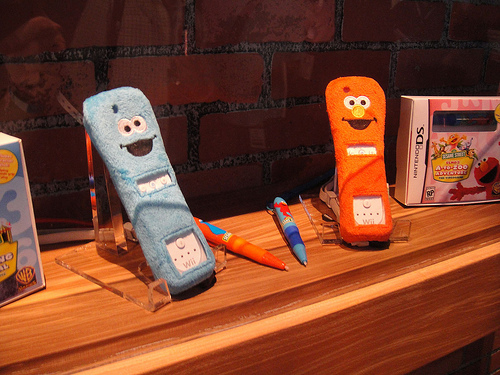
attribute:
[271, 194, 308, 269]
stylus pen — blue, purple, orange, Elmo, monster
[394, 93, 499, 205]
ds game — pink, Nintendo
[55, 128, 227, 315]
plastic stand — clear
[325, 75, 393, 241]
wii game — monster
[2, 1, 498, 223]
brick wall — red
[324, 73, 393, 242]
orange cover — cloth, fuzzy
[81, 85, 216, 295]
blue cover — cloth, fuzzy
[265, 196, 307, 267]
blue pen — colorful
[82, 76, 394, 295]
wii remotes — kid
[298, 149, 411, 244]
remote holder — clear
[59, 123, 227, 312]
stand — plastic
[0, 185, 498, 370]
table — wooden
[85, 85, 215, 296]
controller — blue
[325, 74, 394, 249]
controller — orange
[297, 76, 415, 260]
phone — toy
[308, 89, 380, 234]
cover — orange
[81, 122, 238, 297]
phone — toy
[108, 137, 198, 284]
cover — blue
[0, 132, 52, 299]
box — toy